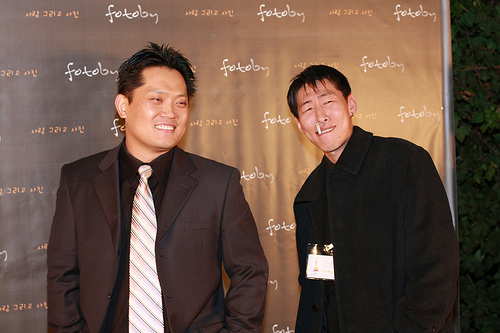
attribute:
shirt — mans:
[100, 121, 233, 331]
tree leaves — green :
[450, 2, 499, 330]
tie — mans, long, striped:
[126, 167, 167, 331]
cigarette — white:
[316, 122, 321, 135]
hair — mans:
[118, 41, 195, 98]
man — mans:
[286, 63, 458, 331]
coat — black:
[292, 125, 459, 330]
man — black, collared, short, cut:
[32, 43, 278, 331]